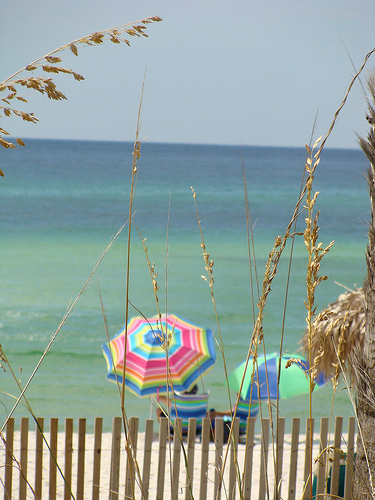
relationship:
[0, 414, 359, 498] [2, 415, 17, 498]
fence has slat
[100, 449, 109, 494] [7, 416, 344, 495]
sand on sandy beach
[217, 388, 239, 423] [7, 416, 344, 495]
person on sandy beach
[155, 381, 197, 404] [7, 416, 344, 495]
person on sandy beach